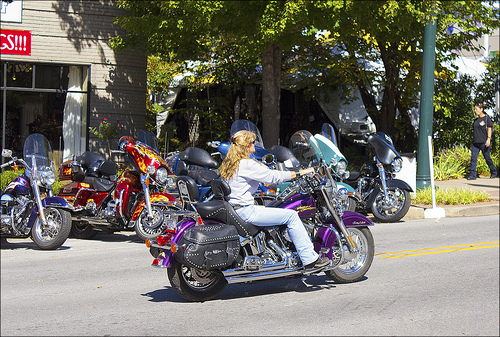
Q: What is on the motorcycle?
A: A woman.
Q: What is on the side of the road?
A: Parked motorcycles.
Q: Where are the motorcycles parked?
A: In front of a bush.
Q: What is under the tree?
A: A tent.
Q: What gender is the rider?
A: A female.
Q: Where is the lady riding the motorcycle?
A: On the street.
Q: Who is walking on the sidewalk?
A: A pedestrian.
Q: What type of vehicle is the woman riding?
A: A motorcycle.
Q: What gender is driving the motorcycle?
A: Female.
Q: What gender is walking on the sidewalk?
A: A female.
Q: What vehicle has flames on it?
A: Red motorcycle.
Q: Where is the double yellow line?
A: On the road.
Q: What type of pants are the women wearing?
A: Jeans.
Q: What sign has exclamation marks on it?
A: The red and white sign.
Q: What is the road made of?
A: Asphalt.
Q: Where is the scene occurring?
A: City street.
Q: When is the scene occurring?
A: During the day.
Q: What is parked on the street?
A: Motorcycles.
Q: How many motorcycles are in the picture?
A: 6.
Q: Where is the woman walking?
A: On the sidewalk.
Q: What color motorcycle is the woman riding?
A: Purple.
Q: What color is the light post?
A: Green.